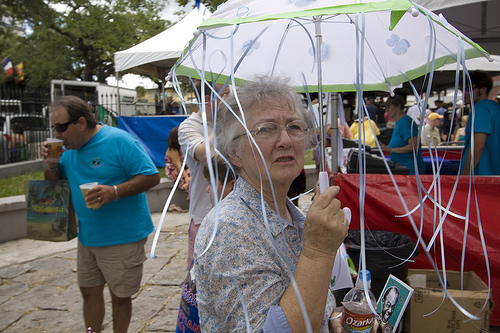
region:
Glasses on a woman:
[211, 108, 324, 177]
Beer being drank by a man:
[31, 134, 68, 169]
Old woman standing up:
[198, 68, 352, 331]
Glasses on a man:
[36, 93, 102, 149]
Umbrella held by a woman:
[156, 4, 487, 234]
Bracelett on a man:
[108, 178, 125, 205]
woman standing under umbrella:
[188, 78, 375, 331]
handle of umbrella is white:
[314, 168, 357, 236]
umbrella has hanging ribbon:
[163, 1, 498, 328]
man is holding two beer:
[36, 93, 163, 332]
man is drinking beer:
[37, 95, 164, 332]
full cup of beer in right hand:
[43, 135, 65, 165]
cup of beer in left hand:
[74, 175, 101, 215]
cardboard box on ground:
[400, 258, 492, 331]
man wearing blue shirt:
[51, 120, 160, 250]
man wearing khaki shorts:
[69, 230, 149, 303]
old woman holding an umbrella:
[171, 0, 337, 331]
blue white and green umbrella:
[172, 0, 493, 192]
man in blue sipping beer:
[40, 95, 159, 331]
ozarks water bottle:
[342, 268, 375, 331]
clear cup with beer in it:
[44, 135, 63, 166]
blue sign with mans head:
[371, 275, 413, 331]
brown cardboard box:
[406, 266, 490, 331]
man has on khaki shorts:
[76, 236, 147, 296]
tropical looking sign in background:
[23, 178, 75, 240]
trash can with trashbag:
[341, 229, 420, 331]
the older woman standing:
[194, 72, 379, 332]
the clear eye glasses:
[231, 118, 313, 144]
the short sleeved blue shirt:
[54, 119, 159, 244]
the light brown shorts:
[75, 230, 148, 297]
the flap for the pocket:
[122, 249, 146, 284]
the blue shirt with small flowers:
[194, 175, 336, 332]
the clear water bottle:
[340, 268, 375, 331]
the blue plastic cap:
[357, 265, 367, 277]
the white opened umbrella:
[166, 0, 492, 222]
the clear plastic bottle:
[340, 265, 377, 331]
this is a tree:
[51, 6, 173, 90]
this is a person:
[28, 85, 159, 325]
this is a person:
[182, 69, 373, 328]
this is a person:
[155, 70, 285, 288]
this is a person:
[328, 94, 388, 165]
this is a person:
[377, 89, 443, 201]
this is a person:
[448, 69, 493, 160]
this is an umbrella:
[163, 5, 492, 108]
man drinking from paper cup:
[12, 91, 163, 331]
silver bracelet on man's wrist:
[108, 180, 123, 203]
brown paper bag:
[18, 160, 80, 246]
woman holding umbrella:
[160, 0, 498, 331]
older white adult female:
[185, 73, 403, 330]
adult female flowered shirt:
[177, 173, 362, 331]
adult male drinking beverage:
[20, 93, 169, 332]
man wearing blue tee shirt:
[14, 90, 163, 331]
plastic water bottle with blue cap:
[339, 265, 385, 332]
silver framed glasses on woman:
[226, 113, 312, 154]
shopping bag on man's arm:
[16, 170, 81, 248]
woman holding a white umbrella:
[178, 77, 360, 327]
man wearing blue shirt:
[44, 97, 152, 332]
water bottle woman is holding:
[342, 263, 380, 331]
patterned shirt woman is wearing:
[203, 183, 329, 332]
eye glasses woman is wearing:
[235, 120, 308, 143]